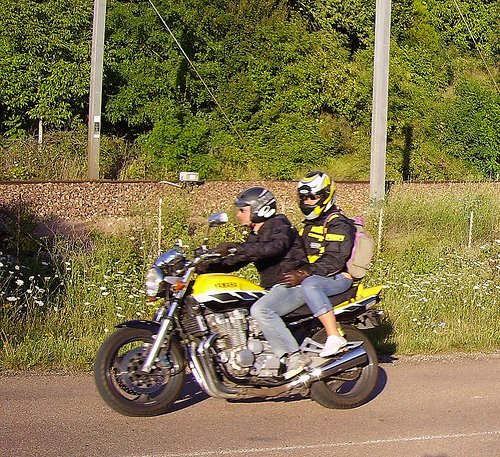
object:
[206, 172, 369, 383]
couple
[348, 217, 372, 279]
brown backpack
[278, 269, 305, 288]
leather gloves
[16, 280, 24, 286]
white flower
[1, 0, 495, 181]
green trees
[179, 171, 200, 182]
electrical box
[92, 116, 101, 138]
white sign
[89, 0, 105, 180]
wooden pole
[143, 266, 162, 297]
headlight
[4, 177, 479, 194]
railroad tracks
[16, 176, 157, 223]
gravel rocks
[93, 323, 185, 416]
black tire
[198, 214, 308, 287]
black jacket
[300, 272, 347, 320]
blue jeans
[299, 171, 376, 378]
woman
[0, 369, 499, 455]
highway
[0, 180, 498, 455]
ground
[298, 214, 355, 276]
jacket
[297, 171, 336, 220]
motorcycle helmet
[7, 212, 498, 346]
flowers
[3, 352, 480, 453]
road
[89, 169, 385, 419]
motorcycle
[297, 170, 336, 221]
helmet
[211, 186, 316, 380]
person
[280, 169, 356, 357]
person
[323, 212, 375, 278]
backpack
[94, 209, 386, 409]
bike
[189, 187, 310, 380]
man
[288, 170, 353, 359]
lady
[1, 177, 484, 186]
track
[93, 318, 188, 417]
wheel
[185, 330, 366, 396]
muffler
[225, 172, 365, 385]
two people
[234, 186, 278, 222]
protective helmet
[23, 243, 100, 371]
tall grass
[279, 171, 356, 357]
passenger